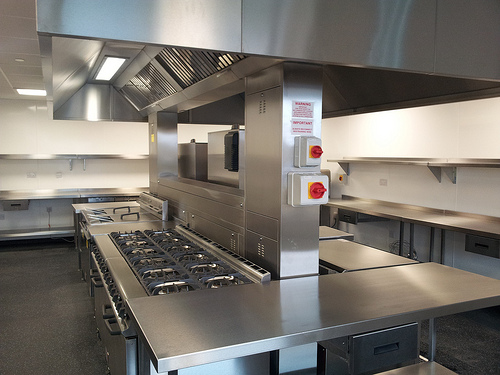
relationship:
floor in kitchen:
[7, 250, 73, 372] [2, 2, 497, 373]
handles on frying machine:
[81, 194, 157, 224] [78, 191, 172, 299]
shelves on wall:
[1, 151, 150, 161] [0, 98, 150, 243]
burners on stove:
[106, 227, 254, 296] [87, 224, 272, 374]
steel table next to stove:
[125, 261, 497, 373] [87, 224, 272, 374]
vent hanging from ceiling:
[115, 63, 177, 112] [0, 0, 498, 115]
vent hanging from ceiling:
[154, 43, 258, 93] [0, 0, 498, 115]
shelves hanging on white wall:
[2, 151, 150, 163] [0, 102, 242, 223]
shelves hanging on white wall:
[2, 186, 154, 200] [0, 102, 242, 223]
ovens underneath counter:
[68, 238, 157, 371] [136, 287, 275, 357]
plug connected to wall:
[359, 160, 403, 215] [357, 167, 424, 198]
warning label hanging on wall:
[290, 97, 314, 134] [283, 75, 323, 135]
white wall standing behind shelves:
[18, 140, 125, 207] [1, 186, 154, 203]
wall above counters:
[0, 103, 148, 153] [0, 150, 147, 201]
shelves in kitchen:
[1, 151, 150, 161] [18, 27, 485, 359]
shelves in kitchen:
[336, 155, 498, 174] [18, 27, 485, 359]